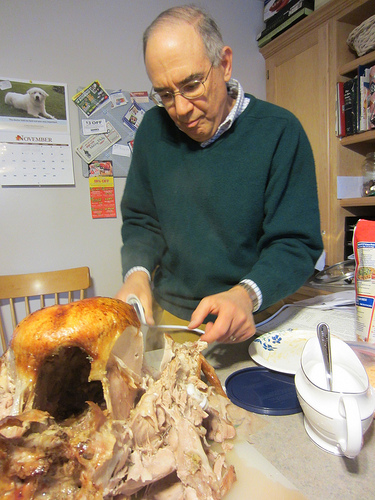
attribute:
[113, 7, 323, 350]
man — balding, grey haired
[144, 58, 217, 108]
glasses — a pair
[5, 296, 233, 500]
turkey — carved, cut, large, partially eaten, partially carved, brown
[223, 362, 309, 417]
lid — blue, plastic, brown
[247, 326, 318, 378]
saucer — blue, white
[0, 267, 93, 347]
chair — wooden, brown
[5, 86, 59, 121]
dog — laying, white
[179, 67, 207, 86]
eyebrow — bushy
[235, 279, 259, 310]
watch — silver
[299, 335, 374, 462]
gravy bowl — white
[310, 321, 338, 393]
utensil — silver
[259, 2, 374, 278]
cabinet — tall, brown, in background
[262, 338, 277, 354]
flower — blue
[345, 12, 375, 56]
basket — wicker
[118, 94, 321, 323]
sweater — green